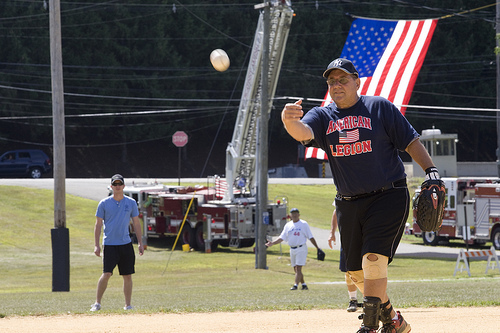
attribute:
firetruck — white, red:
[107, 0, 294, 254]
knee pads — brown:
[345, 247, 396, 298]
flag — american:
[298, 8, 435, 170]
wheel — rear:
[488, 223, 498, 246]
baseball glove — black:
[316, 248, 326, 260]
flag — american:
[335, 7, 457, 138]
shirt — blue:
[93, 195, 143, 248]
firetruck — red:
[107, 177, 289, 254]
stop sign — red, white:
[170, 129, 188, 147]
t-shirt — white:
[276, 217, 316, 247]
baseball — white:
[214, 49, 236, 76]